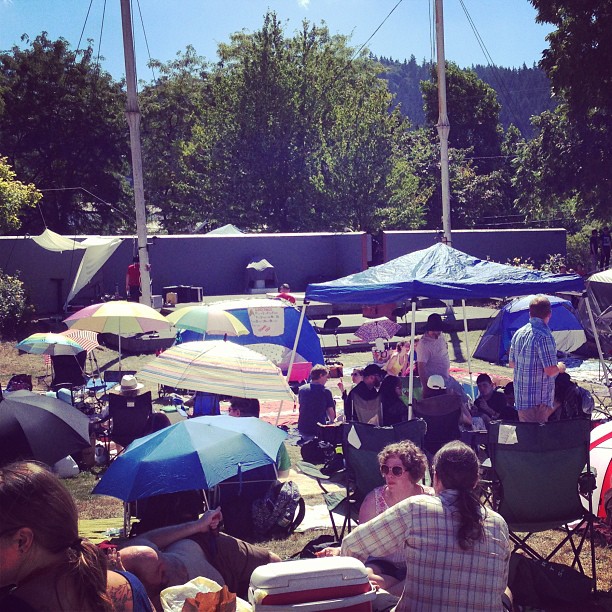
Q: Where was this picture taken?
A: At a park.